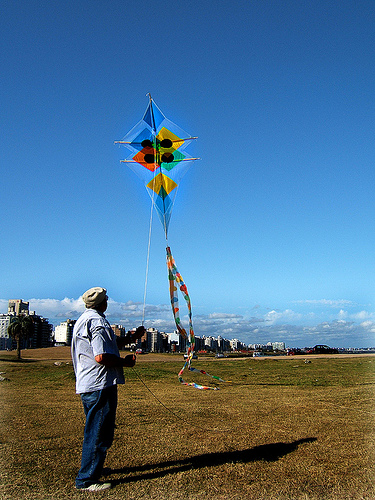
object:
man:
[62, 287, 146, 493]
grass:
[0, 352, 374, 500]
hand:
[125, 355, 136, 369]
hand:
[133, 325, 146, 339]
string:
[135, 165, 156, 350]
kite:
[112, 92, 222, 397]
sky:
[3, 3, 374, 343]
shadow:
[105, 435, 318, 486]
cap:
[82, 285, 109, 309]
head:
[82, 286, 108, 311]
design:
[113, 91, 200, 241]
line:
[128, 363, 251, 435]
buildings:
[52, 316, 287, 357]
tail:
[164, 241, 214, 392]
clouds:
[2, 297, 371, 341]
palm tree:
[7, 315, 33, 363]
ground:
[0, 350, 373, 494]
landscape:
[5, 351, 373, 370]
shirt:
[69, 310, 124, 395]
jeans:
[73, 385, 118, 490]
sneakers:
[75, 478, 111, 495]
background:
[0, 1, 373, 499]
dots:
[173, 296, 177, 305]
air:
[270, 187, 369, 303]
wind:
[2, 6, 373, 497]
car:
[308, 344, 330, 355]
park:
[0, 350, 374, 498]